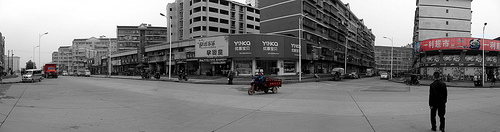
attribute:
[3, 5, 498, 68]
sky — cloudy , grey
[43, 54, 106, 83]
cars — parked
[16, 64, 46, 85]
automobile — metallic grey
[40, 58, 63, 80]
truck — big, red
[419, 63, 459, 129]
person — lone, walking